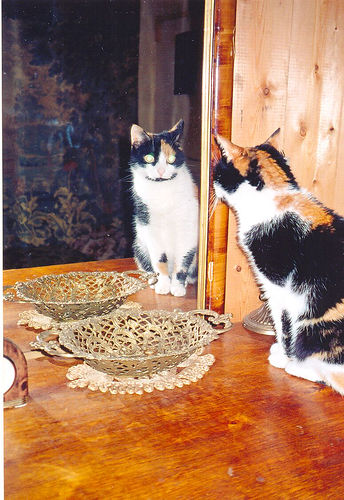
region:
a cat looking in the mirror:
[25, 108, 322, 430]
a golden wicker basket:
[37, 299, 228, 380]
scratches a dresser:
[221, 448, 273, 487]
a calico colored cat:
[219, 140, 338, 382]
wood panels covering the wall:
[269, 17, 315, 129]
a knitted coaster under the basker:
[80, 370, 124, 382]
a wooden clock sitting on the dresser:
[7, 336, 33, 422]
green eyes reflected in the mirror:
[143, 155, 180, 164]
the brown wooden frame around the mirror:
[218, 7, 246, 128]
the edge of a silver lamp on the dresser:
[243, 307, 270, 335]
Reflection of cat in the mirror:
[124, 120, 203, 295]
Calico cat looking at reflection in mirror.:
[124, 116, 341, 395]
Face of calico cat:
[125, 118, 190, 184]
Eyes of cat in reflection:
[140, 148, 176, 165]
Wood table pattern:
[73, 407, 308, 487]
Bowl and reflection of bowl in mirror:
[0, 270, 231, 395]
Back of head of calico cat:
[206, 127, 307, 207]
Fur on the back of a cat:
[246, 153, 336, 265]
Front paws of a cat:
[149, 266, 191, 298]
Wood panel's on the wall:
[244, 20, 330, 124]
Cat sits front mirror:
[210, 126, 343, 396]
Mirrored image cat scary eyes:
[124, 116, 208, 296]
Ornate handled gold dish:
[13, 259, 150, 322]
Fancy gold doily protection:
[66, 356, 217, 398]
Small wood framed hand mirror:
[2, 330, 41, 428]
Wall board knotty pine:
[244, 10, 341, 147]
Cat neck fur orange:
[240, 137, 322, 239]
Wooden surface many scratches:
[68, 397, 315, 483]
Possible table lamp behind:
[241, 280, 284, 343]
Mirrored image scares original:
[130, 121, 190, 186]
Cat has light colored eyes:
[138, 150, 192, 170]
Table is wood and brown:
[167, 412, 302, 486]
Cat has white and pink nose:
[150, 160, 174, 182]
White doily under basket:
[56, 343, 223, 398]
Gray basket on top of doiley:
[83, 311, 218, 381]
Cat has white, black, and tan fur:
[252, 324, 340, 404]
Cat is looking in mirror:
[146, 124, 310, 274]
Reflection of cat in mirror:
[79, 79, 194, 337]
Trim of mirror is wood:
[199, 37, 275, 114]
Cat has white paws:
[151, 278, 196, 302]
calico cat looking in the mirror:
[212, 127, 342, 398]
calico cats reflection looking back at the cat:
[126, 115, 197, 295]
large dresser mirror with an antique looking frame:
[2, 0, 230, 334]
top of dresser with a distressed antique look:
[0, 323, 343, 498]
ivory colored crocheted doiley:
[64, 346, 215, 391]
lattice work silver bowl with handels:
[31, 308, 232, 374]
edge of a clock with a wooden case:
[0, 340, 28, 409]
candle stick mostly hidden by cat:
[242, 294, 275, 337]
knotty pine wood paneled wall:
[228, 0, 343, 323]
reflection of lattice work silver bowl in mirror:
[5, 271, 155, 317]